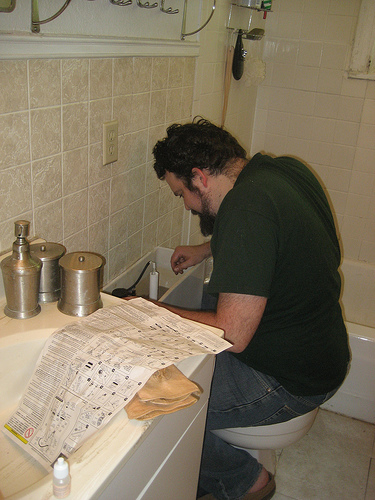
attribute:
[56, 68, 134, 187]
wall — tiled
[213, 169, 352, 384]
shirt — black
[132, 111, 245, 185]
hair — curly